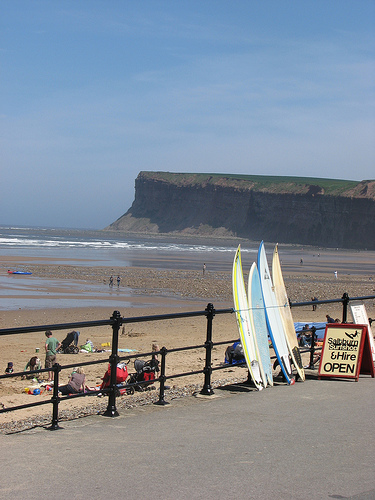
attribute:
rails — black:
[12, 292, 374, 430]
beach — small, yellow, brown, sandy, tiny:
[4, 241, 373, 419]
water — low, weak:
[3, 221, 276, 279]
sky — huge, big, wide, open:
[1, 8, 374, 222]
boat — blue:
[6, 262, 33, 281]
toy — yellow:
[18, 383, 42, 399]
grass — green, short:
[164, 167, 357, 190]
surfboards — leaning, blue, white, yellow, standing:
[230, 235, 312, 401]